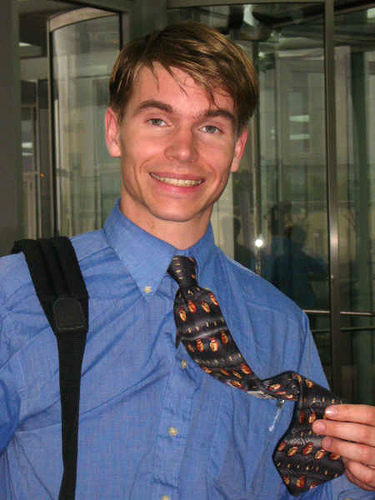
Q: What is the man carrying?
A: Black shoulder strap over shoulder.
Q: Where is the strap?
A: On the shoulder.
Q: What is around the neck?
A: A man's blue shirt collar.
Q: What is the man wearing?
A: Man is wearing tie.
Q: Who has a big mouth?
A: A man.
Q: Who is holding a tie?
A: A man.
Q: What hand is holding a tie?
A: Left hand.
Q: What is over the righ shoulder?
A: A strap.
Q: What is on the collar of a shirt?
A: A button.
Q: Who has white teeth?
A: A man.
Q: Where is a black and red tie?
A: On a shirt.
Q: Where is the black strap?
A: Over a shirt.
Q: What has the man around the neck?
A: A tie.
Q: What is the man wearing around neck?
A: A tie.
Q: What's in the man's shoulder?
A: Black strap.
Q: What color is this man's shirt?
A: Blue.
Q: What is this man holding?
A: Tie.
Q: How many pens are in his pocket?
A: 1.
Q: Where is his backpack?
A: On his shoulder.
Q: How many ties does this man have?
A: 1.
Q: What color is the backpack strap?
A: Black.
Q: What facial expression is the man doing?
A: Smile.